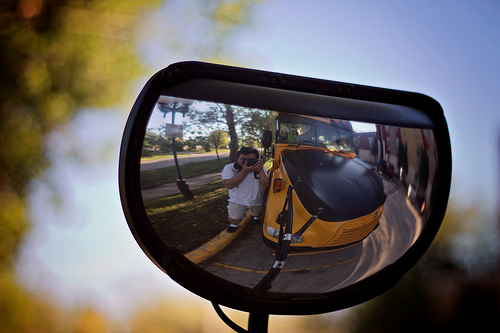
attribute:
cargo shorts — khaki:
[222, 196, 273, 242]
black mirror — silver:
[250, 123, 286, 159]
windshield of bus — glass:
[253, 118, 370, 157]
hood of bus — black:
[282, 136, 390, 215]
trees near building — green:
[161, 98, 290, 201]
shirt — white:
[227, 160, 270, 204]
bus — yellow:
[262, 140, 388, 250]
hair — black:
[237, 147, 250, 165]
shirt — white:
[227, 152, 266, 218]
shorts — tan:
[226, 195, 273, 235]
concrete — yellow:
[160, 187, 255, 274]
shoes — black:
[221, 217, 277, 236]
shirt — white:
[224, 171, 277, 207]